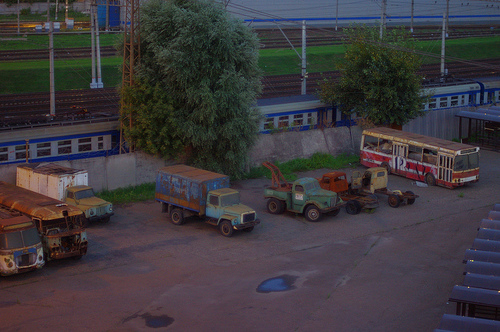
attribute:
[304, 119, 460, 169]
fence — cement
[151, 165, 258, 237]
box truck — old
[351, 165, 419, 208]
truck — flat bed, old, tan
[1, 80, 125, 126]
tracks — train, brown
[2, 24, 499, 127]
train tracks — empty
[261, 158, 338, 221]
tow truck — old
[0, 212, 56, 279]
bus — rusty, old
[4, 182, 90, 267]
bus — rusty, old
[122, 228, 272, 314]
lot — rusty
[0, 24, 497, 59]
tracks — train, brown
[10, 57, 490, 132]
tracks — brown, train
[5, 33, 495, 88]
grass — green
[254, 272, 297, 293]
puddle — shallow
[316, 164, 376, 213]
vehicle — old, rusty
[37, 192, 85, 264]
vehicle — rusty, old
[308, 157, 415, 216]
vehicle — rusty, old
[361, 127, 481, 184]
bus — red, white, antique, parked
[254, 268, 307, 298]
puddle — small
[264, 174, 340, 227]
tow truck — green, old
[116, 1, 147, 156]
tower — metal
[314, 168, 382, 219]
truck — old, red, flat bed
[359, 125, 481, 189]
bus — red, yellow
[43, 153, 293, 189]
wall — concrete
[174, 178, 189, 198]
rust — brown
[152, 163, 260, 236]
truck — blue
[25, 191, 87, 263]
vehicle — old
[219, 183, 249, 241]
front — green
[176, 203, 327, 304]
lot — parking